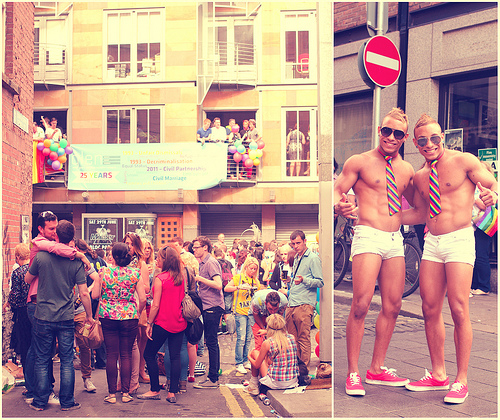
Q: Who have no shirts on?
A: Two guys.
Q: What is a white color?
A: Shorts.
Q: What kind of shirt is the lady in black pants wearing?
A: Red sleeveless.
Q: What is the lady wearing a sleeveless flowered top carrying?
A: A purse.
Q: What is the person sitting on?
A: The curb.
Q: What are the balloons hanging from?
A: The balcony.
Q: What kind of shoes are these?
A: Red and white canvas shoes.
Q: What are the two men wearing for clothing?
A: White shorts and striped neckties.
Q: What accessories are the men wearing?
A: Sunglasses and red shoes.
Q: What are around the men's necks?
A: Ties.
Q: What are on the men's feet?
A: Shoes.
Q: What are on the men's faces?
A: Sunglasses.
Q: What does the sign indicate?
A: No entry.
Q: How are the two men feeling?
A: Happy.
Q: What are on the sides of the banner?
A: Balloons.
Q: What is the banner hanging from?
A: Balconies.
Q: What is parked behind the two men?
A: Bicycle.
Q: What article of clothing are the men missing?
A: Shirts.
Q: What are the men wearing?
A: A colorful tie.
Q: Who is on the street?
A: A crowd of people.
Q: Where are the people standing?
A: On the street.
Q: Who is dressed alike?
A: Two men.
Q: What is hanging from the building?
A: A sign.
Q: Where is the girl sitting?
A: On the curb.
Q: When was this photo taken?
A: During the day.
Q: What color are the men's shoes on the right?
A: Red.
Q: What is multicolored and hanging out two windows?
A: Balloons.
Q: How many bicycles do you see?
A: One.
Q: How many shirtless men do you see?
A: Two.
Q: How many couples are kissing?
A: Two.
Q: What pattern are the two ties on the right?
A: Rainbow.